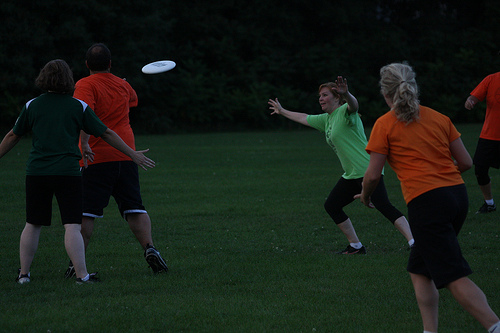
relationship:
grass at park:
[0, 121, 498, 331] [0, 0, 499, 332]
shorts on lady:
[407, 182, 474, 290] [353, 60, 500, 332]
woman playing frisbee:
[267, 74, 415, 252] [142, 59, 177, 74]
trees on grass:
[0, 1, 498, 137] [0, 121, 498, 331]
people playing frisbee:
[0, 41, 499, 331] [142, 59, 177, 74]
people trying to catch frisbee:
[0, 41, 499, 331] [142, 59, 177, 74]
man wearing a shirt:
[65, 43, 169, 279] [72, 74, 139, 167]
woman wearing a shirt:
[267, 74, 415, 252] [306, 101, 386, 179]